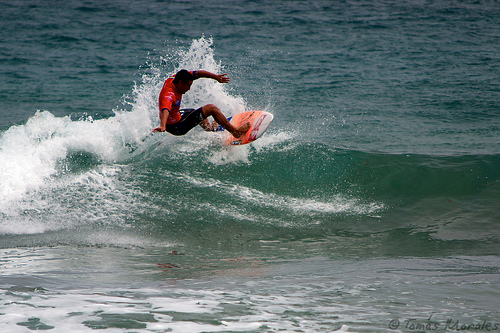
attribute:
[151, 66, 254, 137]
man — surfing, white, male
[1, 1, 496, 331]
ocean — green, large, deep, dark, blue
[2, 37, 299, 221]
foam — white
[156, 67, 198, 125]
shirt — orange, red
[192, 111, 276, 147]
surfboard — white, orange, red, blue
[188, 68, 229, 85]
arm — for balance, extended for balance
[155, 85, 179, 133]
arm — out for balance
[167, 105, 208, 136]
shorts — black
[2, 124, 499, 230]
wave — small, cresting, crested, dark green